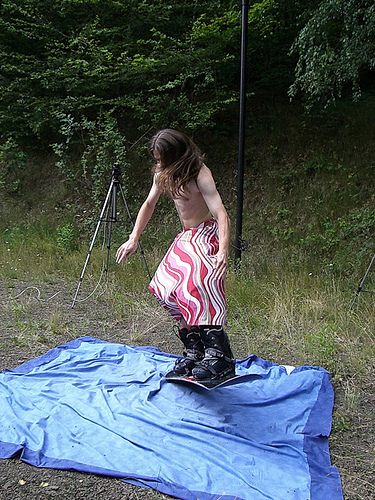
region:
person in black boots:
[122, 115, 256, 415]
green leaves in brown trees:
[23, 23, 84, 75]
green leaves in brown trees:
[249, 38, 276, 66]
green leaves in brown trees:
[310, 149, 361, 214]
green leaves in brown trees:
[140, 33, 183, 74]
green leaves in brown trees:
[22, 31, 46, 61]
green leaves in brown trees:
[180, 39, 245, 66]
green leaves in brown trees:
[75, 21, 111, 57]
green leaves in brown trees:
[112, 7, 165, 50]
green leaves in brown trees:
[13, 53, 86, 120]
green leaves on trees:
[1, 2, 370, 165]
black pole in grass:
[232, 1, 249, 264]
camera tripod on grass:
[69, 161, 155, 309]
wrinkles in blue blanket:
[0, 336, 342, 498]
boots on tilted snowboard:
[166, 321, 257, 389]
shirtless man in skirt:
[119, 128, 231, 324]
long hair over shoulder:
[149, 129, 204, 200]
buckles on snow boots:
[176, 345, 230, 382]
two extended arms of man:
[116, 165, 231, 278]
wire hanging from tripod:
[5, 211, 108, 302]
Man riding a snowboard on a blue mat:
[112, 128, 260, 392]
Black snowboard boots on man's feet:
[173, 323, 234, 381]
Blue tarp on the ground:
[0, 337, 347, 498]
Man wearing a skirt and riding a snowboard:
[117, 129, 262, 389]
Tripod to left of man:
[68, 159, 154, 309]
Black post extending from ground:
[231, 0, 248, 274]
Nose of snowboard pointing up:
[161, 362, 268, 394]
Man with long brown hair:
[150, 128, 203, 205]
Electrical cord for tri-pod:
[2, 209, 110, 303]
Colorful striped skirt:
[149, 223, 226, 323]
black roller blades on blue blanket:
[171, 330, 258, 400]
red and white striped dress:
[155, 236, 226, 328]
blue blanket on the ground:
[9, 392, 334, 484]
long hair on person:
[152, 134, 191, 203]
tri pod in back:
[87, 159, 152, 290]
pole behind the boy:
[238, 1, 244, 269]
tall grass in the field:
[270, 289, 374, 382]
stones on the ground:
[0, 298, 61, 366]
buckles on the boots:
[192, 347, 225, 378]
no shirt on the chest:
[165, 178, 215, 233]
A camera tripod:
[65, 153, 156, 324]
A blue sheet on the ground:
[0, 325, 346, 499]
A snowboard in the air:
[158, 369, 278, 392]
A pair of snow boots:
[168, 321, 240, 378]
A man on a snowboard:
[114, 129, 248, 396]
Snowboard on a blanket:
[163, 369, 287, 415]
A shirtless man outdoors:
[109, 135, 248, 396]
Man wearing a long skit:
[118, 129, 238, 391]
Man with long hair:
[111, 127, 233, 332]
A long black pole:
[235, 2, 254, 259]